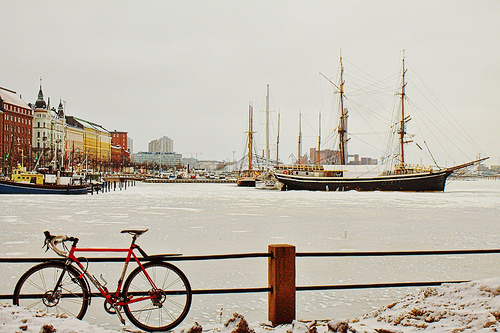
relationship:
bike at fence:
[14, 230, 189, 331] [1, 243, 493, 315]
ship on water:
[275, 41, 492, 192] [2, 177, 498, 328]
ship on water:
[237, 100, 262, 186] [2, 177, 498, 328]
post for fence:
[266, 243, 298, 325] [1, 243, 493, 315]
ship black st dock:
[1, 126, 108, 198] [35, 160, 141, 185]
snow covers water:
[2, 174, 499, 323] [2, 177, 498, 328]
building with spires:
[28, 73, 68, 161] [31, 78, 68, 122]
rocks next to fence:
[149, 309, 401, 333] [1, 243, 493, 315]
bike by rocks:
[14, 230, 189, 331] [149, 309, 401, 333]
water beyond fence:
[2, 177, 498, 328] [1, 243, 493, 315]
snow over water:
[2, 174, 499, 323] [2, 177, 498, 328]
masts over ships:
[245, 47, 445, 169] [239, 157, 485, 191]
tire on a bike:
[124, 262, 193, 329] [14, 230, 189, 331]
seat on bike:
[120, 228, 147, 236] [14, 230, 189, 331]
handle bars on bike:
[40, 230, 78, 263] [14, 230, 189, 331]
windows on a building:
[3, 105, 35, 155] [1, 86, 33, 171]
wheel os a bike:
[13, 261, 90, 319] [14, 230, 189, 331]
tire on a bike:
[13, 261, 90, 319] [14, 230, 189, 331]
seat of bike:
[120, 228, 147, 236] [14, 230, 189, 331]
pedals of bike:
[95, 277, 124, 326] [14, 230, 189, 331]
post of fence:
[266, 243, 298, 325] [1, 243, 493, 315]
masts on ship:
[245, 47, 445, 169] [275, 41, 492, 192]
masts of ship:
[245, 47, 445, 169] [237, 100, 262, 186]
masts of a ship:
[245, 47, 445, 169] [257, 84, 282, 191]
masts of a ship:
[245, 47, 445, 169] [275, 41, 492, 192]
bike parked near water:
[14, 230, 189, 331] [2, 177, 498, 328]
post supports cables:
[266, 243, 298, 325] [298, 243, 500, 294]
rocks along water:
[149, 309, 401, 333] [2, 177, 498, 328]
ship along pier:
[1, 126, 108, 198] [3, 157, 193, 181]